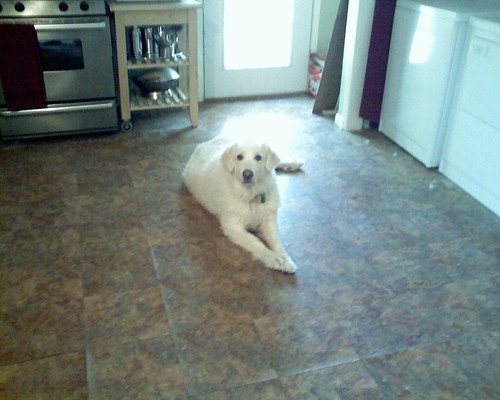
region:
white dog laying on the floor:
[178, 130, 317, 278]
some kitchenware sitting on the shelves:
[118, 7, 205, 128]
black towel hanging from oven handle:
[3, 2, 48, 118]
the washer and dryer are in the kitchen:
[388, 1, 498, 215]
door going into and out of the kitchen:
[204, 2, 319, 99]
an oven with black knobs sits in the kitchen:
[4, 1, 114, 133]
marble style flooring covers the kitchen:
[19, 162, 441, 398]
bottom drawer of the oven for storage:
[5, 104, 119, 135]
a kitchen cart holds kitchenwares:
[105, 2, 210, 134]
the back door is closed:
[206, 1, 313, 101]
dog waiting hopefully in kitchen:
[8, 1, 492, 398]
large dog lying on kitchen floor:
[2, 0, 498, 397]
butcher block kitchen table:
[111, 0, 204, 129]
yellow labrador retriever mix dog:
[181, 128, 304, 274]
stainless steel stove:
[0, 0, 119, 142]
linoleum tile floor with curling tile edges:
[2, 96, 494, 397]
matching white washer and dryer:
[378, 0, 498, 211]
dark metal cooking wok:
[132, 67, 181, 97]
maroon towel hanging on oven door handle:
[0, 22, 46, 111]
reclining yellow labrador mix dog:
[179, 135, 302, 271]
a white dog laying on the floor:
[167, 122, 317, 314]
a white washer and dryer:
[387, 12, 487, 202]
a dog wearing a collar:
[235, 181, 282, 223]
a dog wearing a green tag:
[249, 174, 281, 228]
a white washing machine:
[367, 7, 468, 174]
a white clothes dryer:
[437, 29, 489, 204]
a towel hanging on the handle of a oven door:
[11, 20, 46, 120]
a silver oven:
[36, 3, 106, 165]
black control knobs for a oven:
[10, 1, 106, 21]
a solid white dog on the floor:
[144, 107, 327, 294]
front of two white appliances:
[377, 2, 498, 214]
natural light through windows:
[221, 1, 296, 69]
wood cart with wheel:
[110, 2, 200, 132]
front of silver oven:
[2, 2, 119, 139]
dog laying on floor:
[184, 132, 302, 272]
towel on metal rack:
[2, 22, 49, 112]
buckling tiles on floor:
[2, 286, 186, 397]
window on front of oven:
[37, 35, 84, 71]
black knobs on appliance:
[0, 0, 88, 12]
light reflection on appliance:
[408, 6, 440, 63]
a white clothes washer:
[360, 3, 460, 165]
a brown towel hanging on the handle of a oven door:
[0, 22, 44, 125]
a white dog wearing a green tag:
[240, 182, 298, 222]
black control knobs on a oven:
[0, 2, 105, 22]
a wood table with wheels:
[112, 0, 200, 142]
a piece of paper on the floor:
[415, 158, 462, 216]